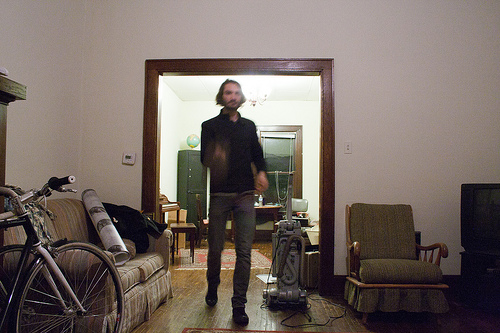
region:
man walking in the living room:
[193, 59, 274, 329]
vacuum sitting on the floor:
[256, 155, 353, 330]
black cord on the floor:
[263, 271, 356, 331]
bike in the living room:
[1, 168, 134, 332]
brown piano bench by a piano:
[151, 188, 201, 267]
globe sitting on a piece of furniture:
[183, 133, 202, 151]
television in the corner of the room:
[451, 174, 499, 256]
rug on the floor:
[169, 228, 276, 275]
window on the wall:
[213, 119, 310, 207]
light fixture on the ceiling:
[236, 77, 278, 109]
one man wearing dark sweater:
[198, 77, 268, 197]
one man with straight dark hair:
[208, 74, 251, 112]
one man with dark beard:
[213, 74, 245, 112]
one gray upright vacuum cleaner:
[266, 184, 315, 316]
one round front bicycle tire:
[3, 239, 129, 330]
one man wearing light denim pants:
[191, 77, 263, 322]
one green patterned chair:
[339, 194, 455, 321]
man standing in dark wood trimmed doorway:
[133, 50, 341, 288]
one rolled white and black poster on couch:
[77, 183, 164, 278]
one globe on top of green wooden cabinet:
[178, 129, 207, 209]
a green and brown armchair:
[315, 181, 462, 324]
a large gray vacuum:
[257, 146, 321, 312]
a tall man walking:
[191, 66, 271, 331]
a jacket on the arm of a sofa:
[103, 200, 180, 252]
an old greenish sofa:
[1, 182, 170, 331]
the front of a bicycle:
[13, 178, 131, 328]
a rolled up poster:
[76, 183, 138, 269]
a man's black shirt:
[187, 110, 290, 193]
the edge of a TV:
[456, 179, 497, 272]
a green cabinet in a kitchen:
[168, 141, 208, 236]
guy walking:
[197, 77, 273, 332]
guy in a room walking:
[48, 28, 440, 330]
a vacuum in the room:
[258, 183, 315, 315]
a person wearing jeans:
[196, 77, 272, 327]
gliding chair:
[339, 198, 459, 328]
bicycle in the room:
[1, 171, 127, 331]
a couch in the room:
[0, 190, 178, 331]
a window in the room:
[258, 122, 301, 216]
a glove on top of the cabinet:
[184, 132, 199, 149]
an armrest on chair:
[418, 240, 453, 264]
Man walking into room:
[202, 76, 269, 326]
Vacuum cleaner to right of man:
[261, 183, 311, 315]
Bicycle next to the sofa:
[2, 174, 125, 331]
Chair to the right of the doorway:
[344, 200, 449, 327]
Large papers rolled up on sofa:
[81, 184, 126, 259]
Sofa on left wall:
[0, 192, 175, 330]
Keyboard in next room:
[157, 192, 181, 257]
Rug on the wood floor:
[169, 249, 274, 270]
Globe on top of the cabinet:
[183, 129, 200, 152]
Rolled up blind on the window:
[255, 127, 298, 142]